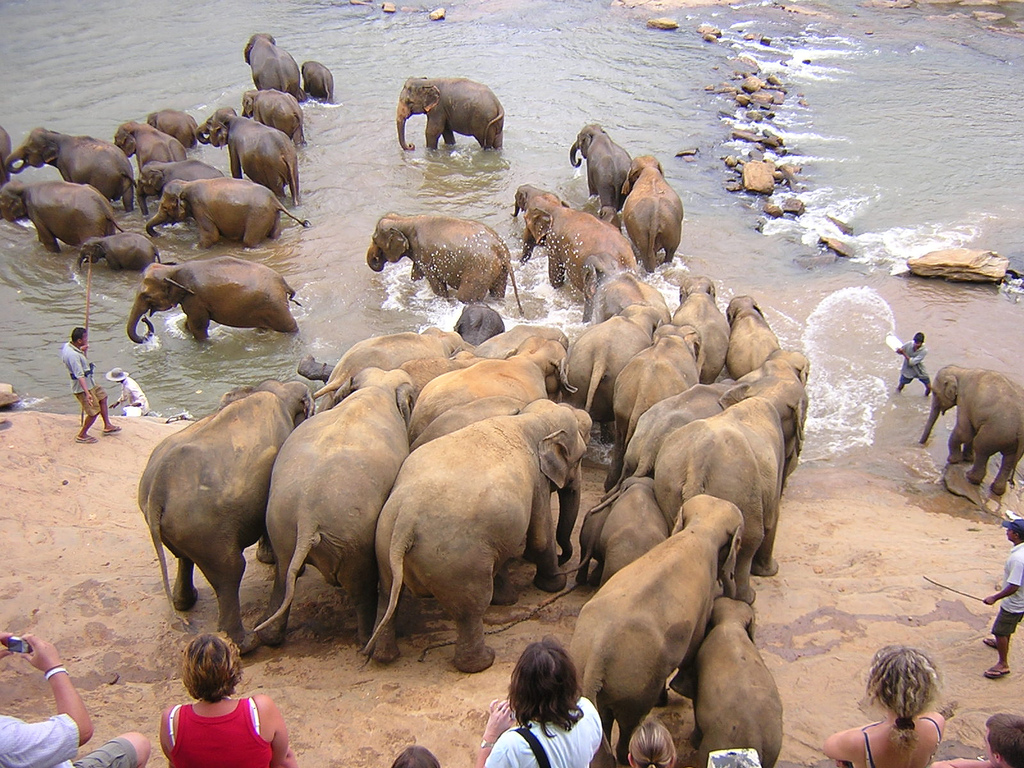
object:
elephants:
[126, 256, 809, 675]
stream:
[0, 0, 1023, 466]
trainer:
[896, 332, 931, 397]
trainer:
[923, 520, 1015, 677]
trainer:
[62, 328, 123, 443]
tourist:
[159, 633, 292, 767]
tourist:
[822, 645, 946, 766]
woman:
[498, 631, 602, 727]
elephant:
[243, 32, 334, 105]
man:
[933, 713, 1018, 766]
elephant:
[0, 180, 162, 275]